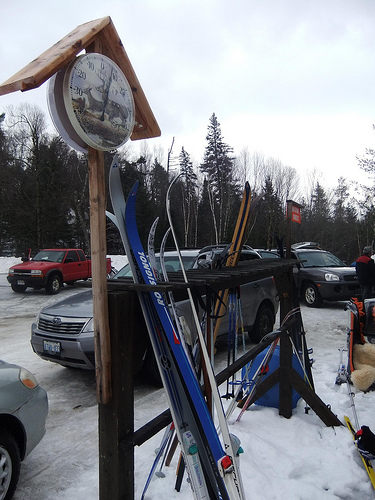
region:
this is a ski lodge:
[99, 261, 273, 496]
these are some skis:
[121, 357, 215, 448]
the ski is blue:
[141, 316, 191, 365]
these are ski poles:
[163, 282, 284, 382]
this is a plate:
[34, 313, 55, 375]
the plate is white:
[8, 309, 53, 357]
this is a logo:
[53, 297, 75, 370]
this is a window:
[9, 237, 95, 261]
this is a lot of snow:
[262, 471, 302, 488]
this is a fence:
[19, 419, 178, 461]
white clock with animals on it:
[51, 49, 146, 159]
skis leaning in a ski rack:
[140, 189, 295, 493]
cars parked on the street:
[2, 193, 356, 473]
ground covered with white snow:
[261, 429, 320, 487]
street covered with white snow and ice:
[4, 261, 92, 477]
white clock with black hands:
[47, 46, 148, 152]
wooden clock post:
[23, 11, 145, 404]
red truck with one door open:
[1, 235, 110, 296]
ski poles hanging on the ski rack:
[219, 279, 251, 404]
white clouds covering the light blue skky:
[173, 27, 334, 110]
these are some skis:
[126, 186, 257, 490]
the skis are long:
[168, 380, 204, 457]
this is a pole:
[52, 160, 90, 278]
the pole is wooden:
[16, 249, 109, 335]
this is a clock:
[74, 68, 142, 145]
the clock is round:
[68, 78, 112, 139]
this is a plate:
[32, 327, 104, 390]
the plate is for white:
[28, 306, 119, 415]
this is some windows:
[35, 223, 91, 299]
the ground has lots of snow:
[241, 377, 290, 462]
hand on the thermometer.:
[93, 70, 117, 118]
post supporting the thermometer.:
[91, 236, 106, 305]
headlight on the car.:
[21, 369, 34, 387]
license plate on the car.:
[39, 341, 65, 353]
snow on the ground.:
[268, 437, 317, 467]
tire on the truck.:
[47, 274, 57, 292]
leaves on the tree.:
[48, 179, 59, 206]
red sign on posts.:
[292, 208, 300, 217]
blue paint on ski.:
[202, 415, 218, 439]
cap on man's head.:
[363, 243, 371, 252]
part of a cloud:
[279, 115, 302, 150]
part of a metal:
[199, 439, 219, 477]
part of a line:
[212, 431, 222, 450]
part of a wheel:
[235, 448, 247, 473]